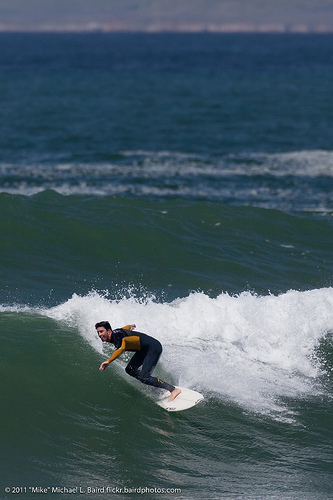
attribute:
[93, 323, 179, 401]
man — crouching, happy, inclined forward, surfer, bending, smiling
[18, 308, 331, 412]
wave — splashing, breaking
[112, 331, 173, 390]
wet suit — camel brown, black, brown, orange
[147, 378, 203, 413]
surfboard — white, white colored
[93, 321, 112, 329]
hair — black, brown, short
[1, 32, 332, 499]
water — green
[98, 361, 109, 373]
hand — extended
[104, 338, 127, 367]
arm — extended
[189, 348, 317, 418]
foam — white